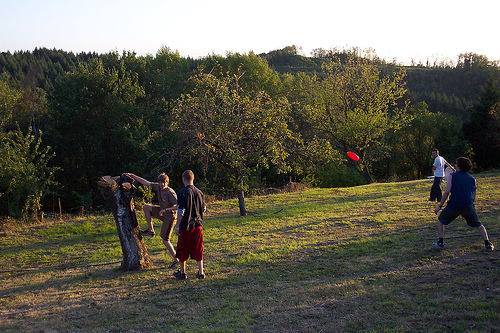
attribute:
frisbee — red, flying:
[343, 149, 364, 163]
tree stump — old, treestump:
[102, 170, 139, 265]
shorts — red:
[175, 229, 208, 265]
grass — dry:
[261, 211, 413, 315]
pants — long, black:
[425, 179, 440, 208]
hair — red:
[159, 173, 172, 184]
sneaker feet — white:
[431, 239, 494, 254]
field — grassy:
[0, 222, 487, 321]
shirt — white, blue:
[427, 158, 447, 182]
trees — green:
[19, 76, 416, 138]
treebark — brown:
[99, 173, 157, 271]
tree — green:
[185, 95, 291, 210]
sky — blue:
[7, 5, 486, 47]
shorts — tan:
[152, 204, 177, 238]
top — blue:
[449, 174, 469, 207]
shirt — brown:
[152, 187, 177, 223]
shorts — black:
[435, 199, 487, 228]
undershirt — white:
[174, 208, 184, 217]